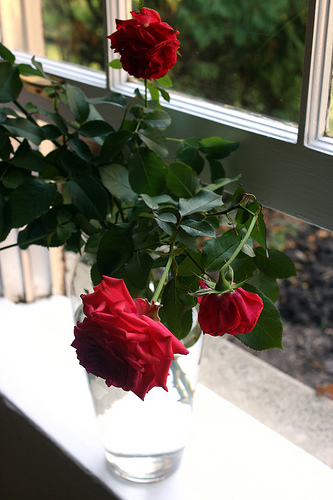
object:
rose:
[107, 7, 182, 82]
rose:
[70, 273, 189, 401]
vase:
[71, 237, 203, 486]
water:
[95, 350, 189, 452]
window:
[116, 2, 300, 121]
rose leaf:
[164, 161, 196, 201]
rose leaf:
[97, 163, 140, 201]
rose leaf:
[64, 81, 90, 123]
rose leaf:
[200, 137, 239, 159]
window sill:
[1, 290, 332, 499]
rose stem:
[171, 355, 194, 403]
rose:
[196, 285, 263, 337]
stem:
[151, 225, 180, 302]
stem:
[219, 203, 261, 288]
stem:
[142, 76, 149, 114]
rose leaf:
[0, 177, 65, 225]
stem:
[52, 89, 68, 150]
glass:
[11, 2, 106, 72]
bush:
[190, 2, 290, 101]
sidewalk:
[203, 318, 331, 466]